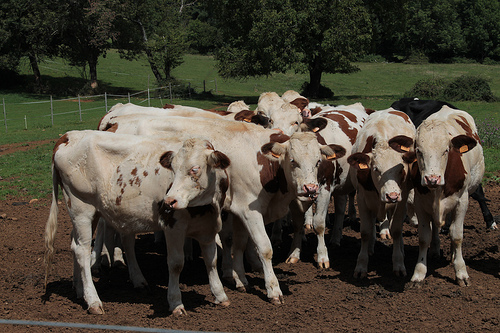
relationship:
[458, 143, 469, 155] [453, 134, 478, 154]
tag on ear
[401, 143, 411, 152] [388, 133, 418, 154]
tag on ear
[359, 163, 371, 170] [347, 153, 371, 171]
tag on ear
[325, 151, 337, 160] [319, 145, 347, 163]
tag on ear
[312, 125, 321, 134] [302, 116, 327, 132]
tag on ear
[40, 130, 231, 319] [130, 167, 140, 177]
calve with spot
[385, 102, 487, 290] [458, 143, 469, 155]
calve has tag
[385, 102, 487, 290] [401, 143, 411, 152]
calve has tag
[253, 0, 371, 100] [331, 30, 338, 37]
tree with green leaf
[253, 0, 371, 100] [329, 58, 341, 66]
tree with green leaf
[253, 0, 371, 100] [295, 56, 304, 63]
tree with green leaf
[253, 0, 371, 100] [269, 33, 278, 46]
tree with green leaf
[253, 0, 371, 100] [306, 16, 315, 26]
tree with green leaf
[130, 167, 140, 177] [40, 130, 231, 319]
spot on calve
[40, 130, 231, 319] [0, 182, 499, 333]
calve standing in dirt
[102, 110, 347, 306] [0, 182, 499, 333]
calve standing in dirt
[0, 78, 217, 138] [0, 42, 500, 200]
fence on grass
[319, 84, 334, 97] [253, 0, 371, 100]
bush next to tree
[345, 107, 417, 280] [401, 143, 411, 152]
calve has tag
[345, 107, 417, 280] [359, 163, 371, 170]
calve has tag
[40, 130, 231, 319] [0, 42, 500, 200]
calve in grass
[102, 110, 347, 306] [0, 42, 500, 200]
calve in grass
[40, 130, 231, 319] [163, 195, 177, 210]
calve has nose